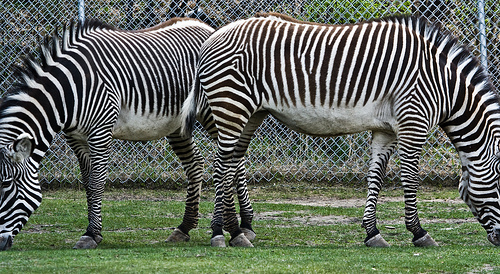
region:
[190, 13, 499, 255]
The zebra is eating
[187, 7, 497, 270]
The zebra is striped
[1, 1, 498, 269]
There are two zebras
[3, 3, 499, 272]
The zebras are eating grass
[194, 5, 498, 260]
The zebra has four legs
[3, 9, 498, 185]
A chain link fence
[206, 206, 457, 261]
Zebras have four hooves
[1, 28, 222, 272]
The zebra is eating grass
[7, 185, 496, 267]
Short green grass is on the ground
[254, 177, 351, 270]
There are patches of dirt in the grass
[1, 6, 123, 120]
black and white zebra mane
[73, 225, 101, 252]
rounded zebra hoof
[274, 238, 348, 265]
patch of flat grass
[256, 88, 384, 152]
white zebra belly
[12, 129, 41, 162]
left ear of the zebra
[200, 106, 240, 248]
black and white striped zebra leg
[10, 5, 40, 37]
silver chain link fence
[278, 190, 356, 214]
patch of dirt on the ground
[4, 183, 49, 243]
round striped zebra jaw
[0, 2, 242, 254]
zebra eating grass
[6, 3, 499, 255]
two zebras in photo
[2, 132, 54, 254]
zebra facing to the left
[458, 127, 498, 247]
zebra facing to the right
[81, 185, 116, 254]
leg of black and white zebra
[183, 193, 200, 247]
leg of black and white zebra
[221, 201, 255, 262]
leg of black and white zebra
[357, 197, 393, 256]
leg of black and white zebra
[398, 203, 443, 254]
leg of black and white zebra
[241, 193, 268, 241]
leg of black and white zebra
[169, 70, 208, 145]
a tail of a zebra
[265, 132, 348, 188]
a chain linked fence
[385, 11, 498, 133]
a zebra's mane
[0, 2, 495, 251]
a pair of zebras grazing in an enclosure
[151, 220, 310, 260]
hooves of a zebra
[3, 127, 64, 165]
a zebra's ear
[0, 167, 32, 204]
a zebra's eye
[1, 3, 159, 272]
a zebra grazing in a zoo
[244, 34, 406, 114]
black and white stripes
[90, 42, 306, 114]
zebra pattern stripes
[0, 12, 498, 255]
sideview of two zebras, butt end to butt end, blending together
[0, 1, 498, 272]
this is a nicer shot than the descriptions will make it sound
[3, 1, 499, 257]
two zebras, blending together, also blending with the chain link fence behind them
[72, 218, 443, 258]
the mingled grey hooves of two zebras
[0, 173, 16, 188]
the black eye of a zebra nibbling grass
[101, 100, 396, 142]
the dusty soft white underbellies of two zebras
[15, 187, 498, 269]
patches of simple dusty earth peeking through the ground's grass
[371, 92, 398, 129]
the slightly striped legpit of the right zebra's right foreleg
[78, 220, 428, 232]
the strip of black hide above all of the mingled hooves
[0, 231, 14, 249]
an open black colour mouth, waiting to be filled with greenery